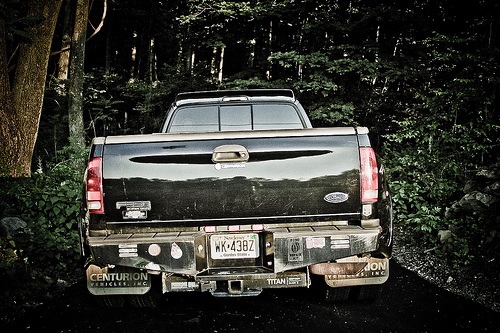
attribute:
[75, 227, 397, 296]
bumper — pictured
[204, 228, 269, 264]
license plate — New Jersey license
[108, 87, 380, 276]
truck — black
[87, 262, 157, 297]
sticker — bumper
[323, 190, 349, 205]
logo — ford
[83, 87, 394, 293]
truck — black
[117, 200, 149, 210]
name — model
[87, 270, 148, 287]
centurion — vivid, word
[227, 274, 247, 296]
trailer mount — pictured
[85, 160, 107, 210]
light — left brake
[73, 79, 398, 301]
truck — black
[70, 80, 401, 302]
pickup truck — Ford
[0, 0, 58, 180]
trunk — tree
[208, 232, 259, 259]
license plate — New Jersey, white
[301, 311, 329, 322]
patch — large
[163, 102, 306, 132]
window — back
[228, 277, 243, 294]
hitch — trailer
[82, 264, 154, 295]
tire flap — rubber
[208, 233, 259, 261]
plate — license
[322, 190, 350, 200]
logo — blue, ford